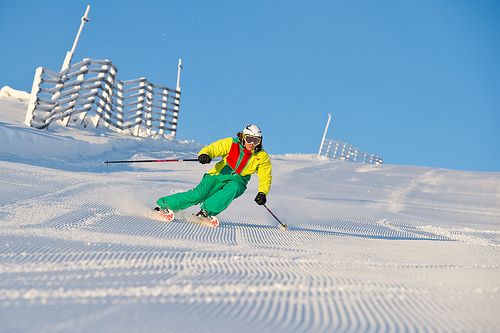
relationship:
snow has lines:
[5, 81, 492, 326] [11, 222, 403, 325]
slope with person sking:
[5, 155, 486, 296] [151, 200, 237, 240]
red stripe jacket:
[226, 139, 255, 175] [196, 139, 275, 201]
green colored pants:
[160, 169, 250, 219] [156, 169, 249, 218]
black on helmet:
[240, 119, 257, 135] [239, 123, 265, 149]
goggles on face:
[242, 132, 261, 147] [244, 136, 263, 153]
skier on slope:
[154, 123, 272, 223] [5, 155, 486, 296]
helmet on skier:
[239, 123, 265, 149] [154, 123, 272, 223]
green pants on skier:
[160, 169, 250, 219] [154, 123, 272, 223]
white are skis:
[149, 212, 225, 229] [155, 204, 225, 230]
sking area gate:
[151, 200, 237, 240] [37, 62, 146, 133]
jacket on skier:
[196, 139, 275, 201] [154, 123, 272, 223]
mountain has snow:
[4, 91, 498, 329] [5, 81, 492, 326]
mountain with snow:
[4, 91, 498, 329] [5, 81, 492, 326]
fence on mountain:
[23, 59, 184, 143] [4, 91, 498, 329]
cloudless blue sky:
[3, 1, 497, 175] [4, 5, 494, 174]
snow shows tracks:
[5, 81, 492, 326] [16, 226, 392, 332]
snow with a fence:
[5, 81, 492, 326] [23, 59, 184, 143]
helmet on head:
[239, 123, 265, 149] [239, 123, 268, 149]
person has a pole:
[154, 123, 272, 223] [105, 151, 209, 168]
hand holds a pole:
[198, 152, 211, 164] [105, 151, 209, 168]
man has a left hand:
[154, 123, 272, 223] [252, 191, 269, 205]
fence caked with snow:
[23, 59, 184, 143] [42, 61, 91, 123]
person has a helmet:
[154, 123, 272, 223] [239, 123, 265, 149]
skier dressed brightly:
[154, 123, 272, 223] [157, 122, 274, 240]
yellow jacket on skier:
[198, 137, 273, 199] [154, 123, 272, 223]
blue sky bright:
[5, 1, 496, 168] [4, 5, 494, 174]